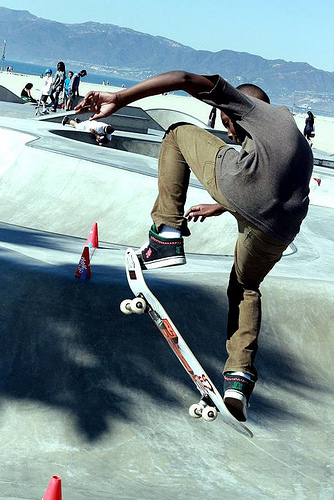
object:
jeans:
[131, 121, 299, 376]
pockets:
[244, 227, 281, 266]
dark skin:
[132, 71, 212, 95]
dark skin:
[183, 205, 225, 220]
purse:
[309, 125, 316, 138]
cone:
[41, 475, 68, 495]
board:
[125, 244, 253, 439]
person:
[20, 78, 40, 102]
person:
[45, 59, 67, 112]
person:
[65, 67, 87, 110]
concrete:
[0, 85, 331, 283]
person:
[62, 115, 114, 144]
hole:
[49, 127, 163, 159]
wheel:
[202, 406, 217, 422]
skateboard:
[116, 241, 255, 445]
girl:
[304, 111, 316, 147]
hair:
[307, 111, 316, 125]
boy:
[96, 70, 314, 423]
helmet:
[45, 68, 52, 74]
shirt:
[196, 70, 315, 242]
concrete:
[31, 259, 332, 438]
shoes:
[138, 225, 185, 271]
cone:
[74, 246, 90, 278]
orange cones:
[77, 248, 90, 276]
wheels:
[105, 295, 145, 315]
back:
[125, 249, 251, 439]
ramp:
[2, 212, 334, 497]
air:
[103, 228, 263, 378]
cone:
[85, 222, 98, 248]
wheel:
[130, 297, 147, 315]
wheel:
[120, 298, 133, 314]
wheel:
[189, 404, 202, 418]